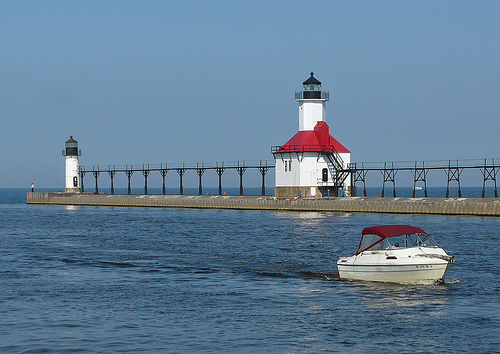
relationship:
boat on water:
[332, 211, 456, 304] [64, 224, 499, 347]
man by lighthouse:
[27, 181, 41, 197] [59, 132, 88, 199]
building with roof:
[260, 53, 357, 229] [274, 125, 350, 163]